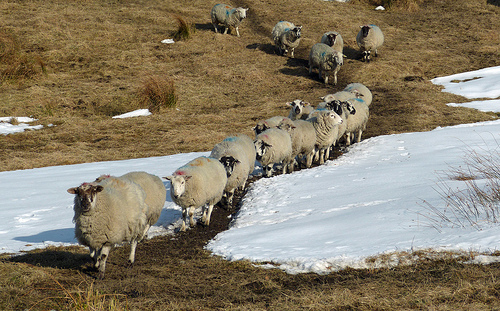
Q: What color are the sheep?
A: White.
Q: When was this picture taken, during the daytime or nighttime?
A: Daytime.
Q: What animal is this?
A: Sheep.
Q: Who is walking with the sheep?
A: No one.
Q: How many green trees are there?
A: None.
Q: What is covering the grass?
A: Snow.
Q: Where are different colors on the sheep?
A: Their backs.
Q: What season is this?
A: WInter.